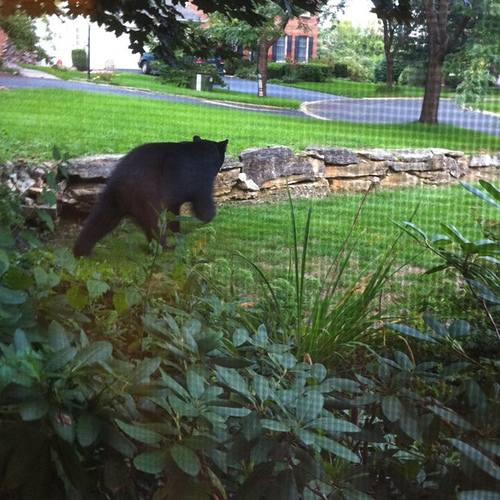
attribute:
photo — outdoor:
[0, 0, 499, 498]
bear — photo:
[67, 134, 228, 257]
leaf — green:
[186, 369, 204, 395]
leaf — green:
[172, 439, 201, 479]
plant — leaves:
[235, 155, 449, 380]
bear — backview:
[71, 125, 235, 263]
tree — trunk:
[409, 53, 452, 133]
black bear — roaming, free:
[72, 134, 229, 264]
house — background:
[181, 0, 347, 77]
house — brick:
[223, 6, 331, 93]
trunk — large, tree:
[418, 7, 484, 134]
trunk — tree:
[255, 47, 272, 98]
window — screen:
[3, 5, 497, 377]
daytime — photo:
[0, 3, 497, 498]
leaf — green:
[127, 353, 162, 381]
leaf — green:
[76, 335, 112, 362]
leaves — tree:
[163, 306, 374, 484]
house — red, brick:
[170, 1, 319, 70]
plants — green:
[163, 219, 405, 418]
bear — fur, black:
[75, 94, 285, 266]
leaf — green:
[306, 415, 362, 437]